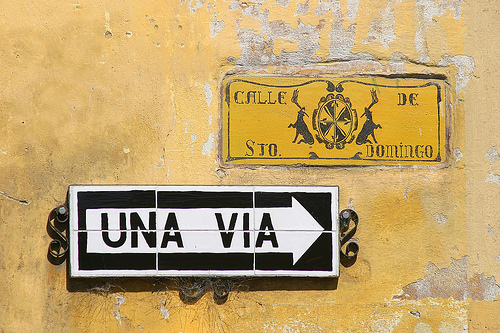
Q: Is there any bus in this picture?
A: No, there are no buses.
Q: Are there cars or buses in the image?
A: No, there are no buses or cars.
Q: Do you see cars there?
A: No, there are no cars.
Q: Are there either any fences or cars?
A: No, there are no cars or fences.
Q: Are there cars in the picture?
A: No, there are no cars.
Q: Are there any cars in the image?
A: No, there are no cars.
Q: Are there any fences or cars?
A: No, there are no cars or fences.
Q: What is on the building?
A: The sign is on the building.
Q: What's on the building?
A: The sign is on the building.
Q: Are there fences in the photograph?
A: No, there are no fences.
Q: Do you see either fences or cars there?
A: No, there are no fences or cars.